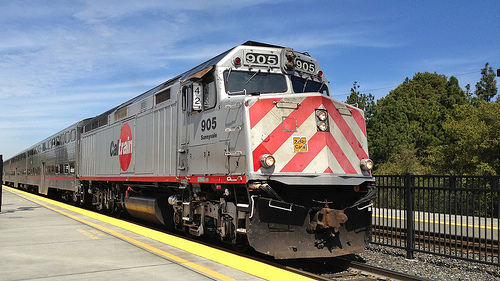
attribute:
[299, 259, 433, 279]
tracks — train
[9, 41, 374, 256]
locomotive — silver , red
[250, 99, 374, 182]
stripes — red, diagonal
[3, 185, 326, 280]
stripe — yellow 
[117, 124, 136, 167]
circle — red 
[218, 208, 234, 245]
wheel — metal 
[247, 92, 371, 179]
stripes — red 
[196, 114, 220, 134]
number — train's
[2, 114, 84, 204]
cars — passenger train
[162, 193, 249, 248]
wheels —  train's